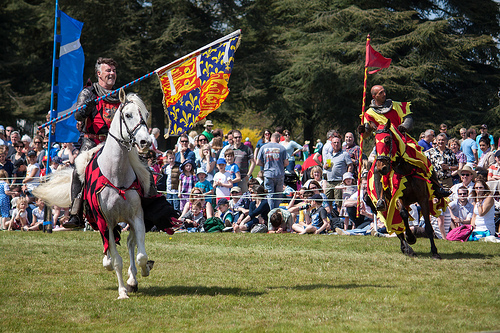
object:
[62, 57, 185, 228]
man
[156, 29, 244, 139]
flag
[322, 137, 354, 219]
person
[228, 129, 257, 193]
person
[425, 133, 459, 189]
person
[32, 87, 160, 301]
horse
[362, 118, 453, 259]
horse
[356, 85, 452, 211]
man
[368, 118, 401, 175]
mask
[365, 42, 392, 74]
flag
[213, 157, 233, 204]
girl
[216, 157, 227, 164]
hat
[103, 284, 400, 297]
shadow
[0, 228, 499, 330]
grass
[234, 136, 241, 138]
sunglasses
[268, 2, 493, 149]
trees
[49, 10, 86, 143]
flag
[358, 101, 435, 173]
costume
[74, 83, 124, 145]
costume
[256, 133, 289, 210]
man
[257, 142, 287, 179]
shirt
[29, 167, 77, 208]
tail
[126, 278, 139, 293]
hoof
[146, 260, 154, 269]
hoof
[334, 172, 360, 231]
child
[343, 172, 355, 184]
hat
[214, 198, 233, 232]
child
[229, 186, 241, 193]
hat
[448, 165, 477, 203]
person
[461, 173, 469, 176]
sunglasses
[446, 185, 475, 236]
person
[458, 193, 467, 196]
sunglasses